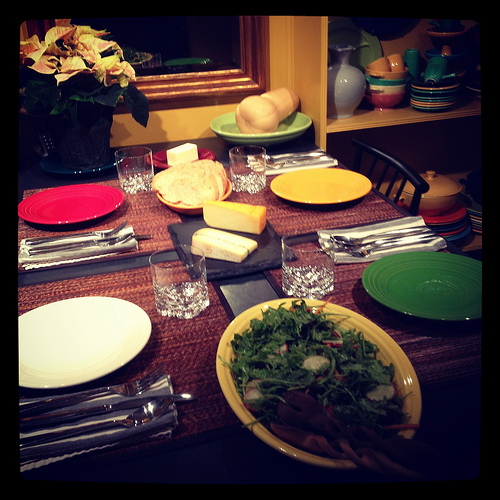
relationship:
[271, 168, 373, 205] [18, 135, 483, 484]
plate on table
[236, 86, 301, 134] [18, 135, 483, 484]
vegetable on table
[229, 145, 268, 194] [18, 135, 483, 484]
glass on table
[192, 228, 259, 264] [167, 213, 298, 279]
cheese on cutting board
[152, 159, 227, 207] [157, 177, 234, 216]
bread in a bowl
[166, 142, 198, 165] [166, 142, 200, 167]
stick of butter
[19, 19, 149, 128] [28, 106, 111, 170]
plant in a pot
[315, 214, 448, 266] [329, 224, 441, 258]
napkin under spoon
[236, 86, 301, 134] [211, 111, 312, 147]
vegetable in bowl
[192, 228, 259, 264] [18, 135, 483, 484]
cheese on table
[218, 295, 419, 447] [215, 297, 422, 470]
salad in bowl